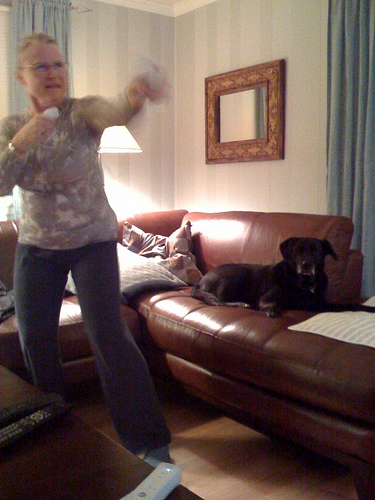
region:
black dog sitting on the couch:
[194, 239, 326, 320]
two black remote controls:
[2, 389, 67, 453]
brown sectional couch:
[6, 210, 374, 452]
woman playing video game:
[1, 27, 186, 466]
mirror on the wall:
[197, 62, 287, 165]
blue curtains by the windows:
[9, 4, 373, 292]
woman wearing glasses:
[0, 28, 171, 470]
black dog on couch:
[190, 209, 373, 480]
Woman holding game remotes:
[1, 32, 174, 470]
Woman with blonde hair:
[2, 33, 171, 471]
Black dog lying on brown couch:
[154, 208, 373, 484]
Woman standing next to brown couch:
[0, 29, 373, 495]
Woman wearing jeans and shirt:
[2, 31, 170, 491]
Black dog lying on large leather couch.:
[181, 206, 373, 473]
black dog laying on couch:
[176, 212, 372, 337]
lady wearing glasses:
[9, 42, 89, 106]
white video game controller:
[115, 437, 198, 498]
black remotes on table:
[0, 383, 90, 462]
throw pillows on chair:
[114, 207, 214, 301]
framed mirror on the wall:
[197, 5, 312, 174]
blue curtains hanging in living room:
[318, 0, 374, 295]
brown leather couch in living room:
[124, 210, 374, 468]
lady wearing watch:
[4, 124, 32, 188]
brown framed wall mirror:
[204, 58, 285, 162]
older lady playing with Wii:
[0, 31, 172, 445]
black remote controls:
[4, 393, 66, 441]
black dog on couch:
[192, 235, 373, 315]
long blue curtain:
[325, 0, 373, 258]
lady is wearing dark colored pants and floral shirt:
[15, 33, 170, 455]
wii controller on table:
[123, 461, 185, 497]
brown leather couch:
[117, 208, 370, 468]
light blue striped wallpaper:
[78, 1, 326, 214]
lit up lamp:
[98, 125, 141, 155]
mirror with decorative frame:
[200, 55, 285, 166]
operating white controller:
[111, 459, 183, 498]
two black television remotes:
[0, 389, 71, 454]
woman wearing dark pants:
[1, 29, 170, 469]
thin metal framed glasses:
[16, 58, 70, 76]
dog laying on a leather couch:
[116, 205, 372, 496]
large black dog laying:
[189, 232, 339, 315]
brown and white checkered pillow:
[117, 215, 199, 279]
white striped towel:
[285, 286, 371, 349]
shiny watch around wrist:
[6, 140, 25, 158]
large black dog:
[189, 234, 340, 319]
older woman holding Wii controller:
[0, 30, 170, 468]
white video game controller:
[38, 59, 166, 125]